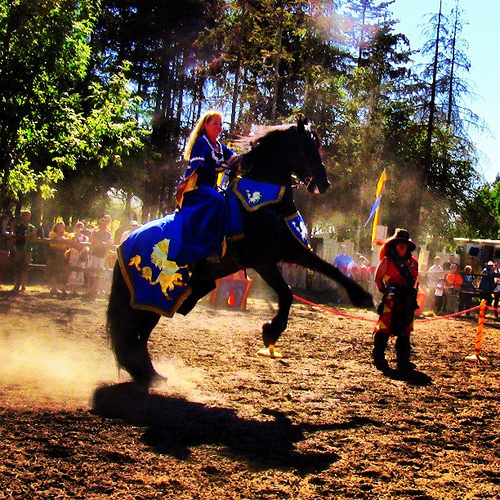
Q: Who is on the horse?
A: A girl.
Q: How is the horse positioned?
A: It is rearing.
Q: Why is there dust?
A: The horse is kicking it up.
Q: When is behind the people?
A: Trees.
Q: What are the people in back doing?
A: Watching.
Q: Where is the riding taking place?
A: In a riding ring.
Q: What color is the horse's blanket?
A: Blue.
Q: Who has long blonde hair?
A: The rider.